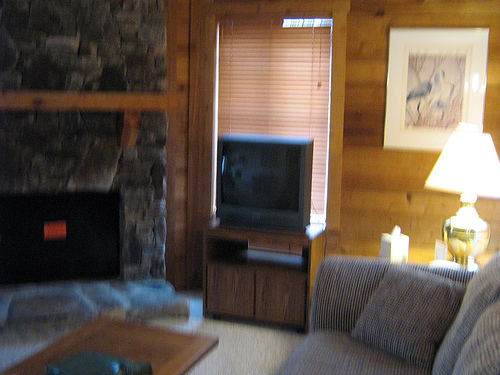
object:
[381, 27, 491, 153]
picture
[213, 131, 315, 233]
tv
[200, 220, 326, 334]
stand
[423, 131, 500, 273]
lamp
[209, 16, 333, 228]
daylight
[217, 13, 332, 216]
blinds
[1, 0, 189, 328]
fireplace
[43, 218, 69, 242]
fire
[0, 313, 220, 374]
table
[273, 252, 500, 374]
couch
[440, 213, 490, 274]
lamp base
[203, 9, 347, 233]
window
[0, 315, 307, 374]
carpet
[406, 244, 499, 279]
table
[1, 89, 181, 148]
shelf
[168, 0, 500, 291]
panelling